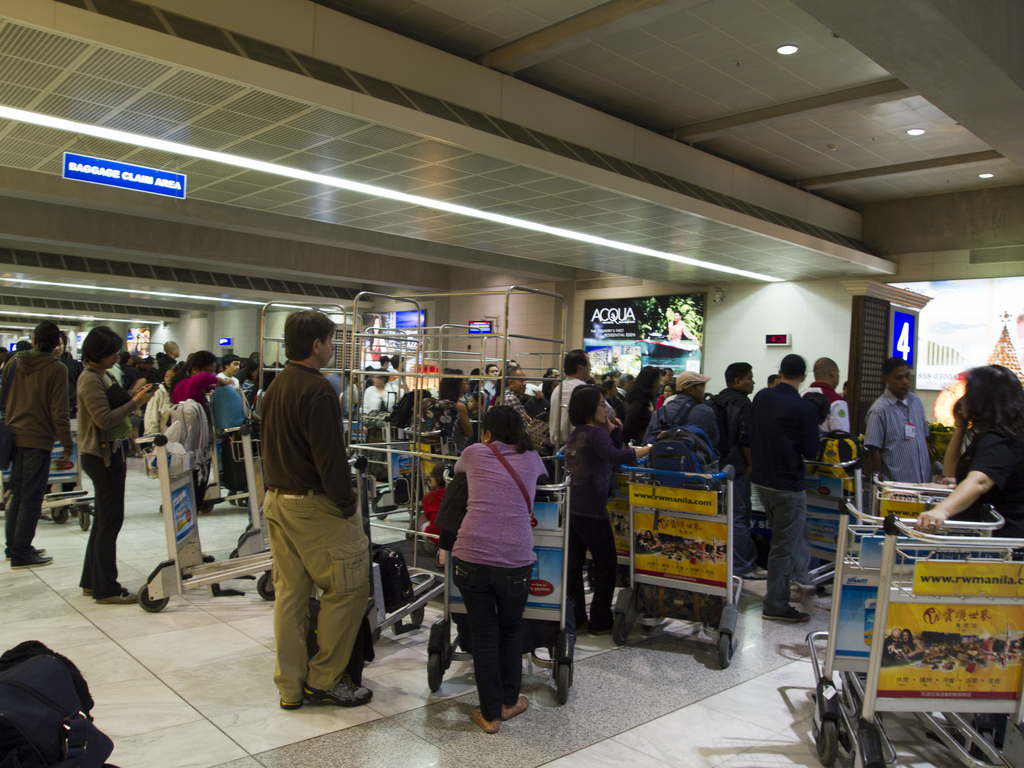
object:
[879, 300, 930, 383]
sign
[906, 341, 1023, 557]
person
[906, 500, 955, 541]
hand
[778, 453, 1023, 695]
luggage cart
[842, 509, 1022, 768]
carts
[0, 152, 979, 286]
baggage claim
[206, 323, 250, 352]
sign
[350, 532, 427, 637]
luggage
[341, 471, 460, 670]
cart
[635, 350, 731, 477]
man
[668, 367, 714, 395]
hat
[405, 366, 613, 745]
woman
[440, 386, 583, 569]
top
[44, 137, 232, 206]
sign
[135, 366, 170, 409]
phone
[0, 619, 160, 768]
bag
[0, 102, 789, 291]
light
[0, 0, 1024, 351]
ceiling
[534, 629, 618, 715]
tile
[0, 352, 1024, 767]
floor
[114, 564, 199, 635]
tile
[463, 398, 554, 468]
hair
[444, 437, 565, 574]
shirt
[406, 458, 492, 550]
bag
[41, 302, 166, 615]
people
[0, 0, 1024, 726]
airport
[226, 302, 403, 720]
man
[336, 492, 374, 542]
hand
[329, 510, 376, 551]
pocket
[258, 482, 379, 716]
pants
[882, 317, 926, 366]
4